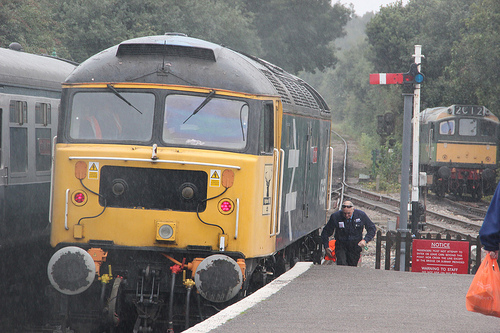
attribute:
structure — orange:
[469, 251, 499, 323]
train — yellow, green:
[412, 106, 499, 196]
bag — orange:
[463, 252, 497, 321]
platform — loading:
[185, 247, 499, 332]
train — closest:
[50, 39, 335, 330]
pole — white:
[362, 20, 429, 229]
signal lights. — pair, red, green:
[405, 68, 425, 85]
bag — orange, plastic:
[456, 227, 492, 329]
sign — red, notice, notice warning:
[407, 234, 472, 276]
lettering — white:
[430, 240, 437, 248]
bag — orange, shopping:
[459, 260, 491, 320]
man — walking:
[317, 192, 380, 267]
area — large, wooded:
[307, 39, 436, 211]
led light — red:
[208, 197, 238, 219]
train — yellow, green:
[410, 100, 499, 202]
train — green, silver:
[1, 40, 81, 258]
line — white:
[167, 250, 342, 330]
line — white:
[182, 254, 317, 331]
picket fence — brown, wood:
[374, 231, 481, 273]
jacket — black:
[321, 209, 373, 247]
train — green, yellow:
[45, 30, 332, 308]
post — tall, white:
[409, 41, 424, 208]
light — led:
[217, 195, 239, 217]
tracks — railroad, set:
[343, 126, 496, 274]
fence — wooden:
[360, 215, 490, 274]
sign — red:
[402, 234, 471, 277]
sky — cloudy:
[302, 2, 438, 48]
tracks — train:
[333, 125, 492, 248]